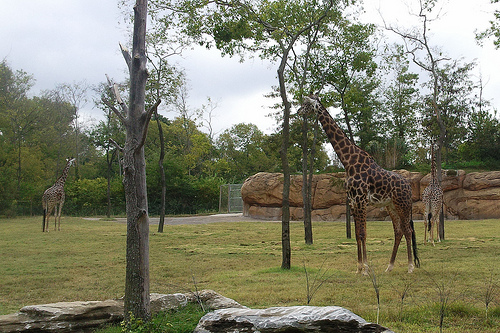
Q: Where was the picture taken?
A: In a zoo.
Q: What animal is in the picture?
A: A giraffe.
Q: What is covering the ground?
A: Grass.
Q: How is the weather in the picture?
A: Cloudy.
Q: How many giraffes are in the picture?
A: 3.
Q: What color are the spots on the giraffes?
A: Brown.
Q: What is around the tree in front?
A: Rocks.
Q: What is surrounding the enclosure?
A: Trees.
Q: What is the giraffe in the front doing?
A: Eating.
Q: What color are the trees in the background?
A: Green.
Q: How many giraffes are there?
A: 3.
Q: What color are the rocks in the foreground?
A: Grey.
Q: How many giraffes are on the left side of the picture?
A: 1.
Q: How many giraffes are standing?
A: 3.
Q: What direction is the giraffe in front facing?
A: Left.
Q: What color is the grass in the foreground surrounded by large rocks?
A: Green.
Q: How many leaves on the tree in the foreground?
A: None.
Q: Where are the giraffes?
A: In a zoo.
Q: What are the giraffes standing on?
A: Grass.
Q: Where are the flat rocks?
A: Around the bottom of the tree.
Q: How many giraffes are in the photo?
A: Three.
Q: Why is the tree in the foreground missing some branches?
A: The giraffes chewed them off.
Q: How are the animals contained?
A: A fence.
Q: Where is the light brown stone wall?
A: Behind the giraffes.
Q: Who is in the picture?
A: No one.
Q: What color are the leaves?
A: Green.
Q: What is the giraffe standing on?
A: Grass.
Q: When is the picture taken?
A: Daytime.